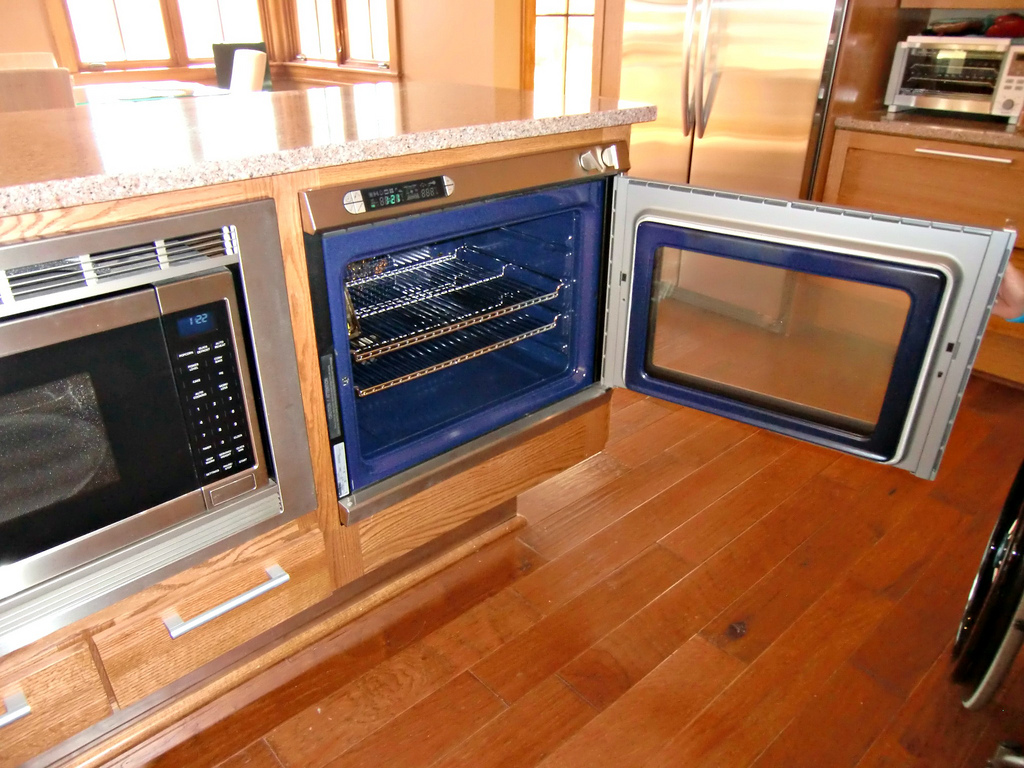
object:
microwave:
[0, 194, 323, 652]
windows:
[57, 0, 261, 76]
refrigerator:
[611, 0, 847, 198]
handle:
[158, 562, 292, 639]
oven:
[301, 173, 1018, 527]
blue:
[301, 175, 610, 500]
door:
[599, 176, 1018, 483]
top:
[0, 74, 654, 250]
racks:
[343, 227, 560, 400]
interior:
[302, 173, 610, 501]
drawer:
[85, 525, 335, 711]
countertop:
[0, 64, 655, 222]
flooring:
[137, 292, 1024, 768]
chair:
[211, 43, 268, 91]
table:
[0, 79, 231, 117]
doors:
[618, 0, 842, 202]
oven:
[882, 34, 1024, 127]